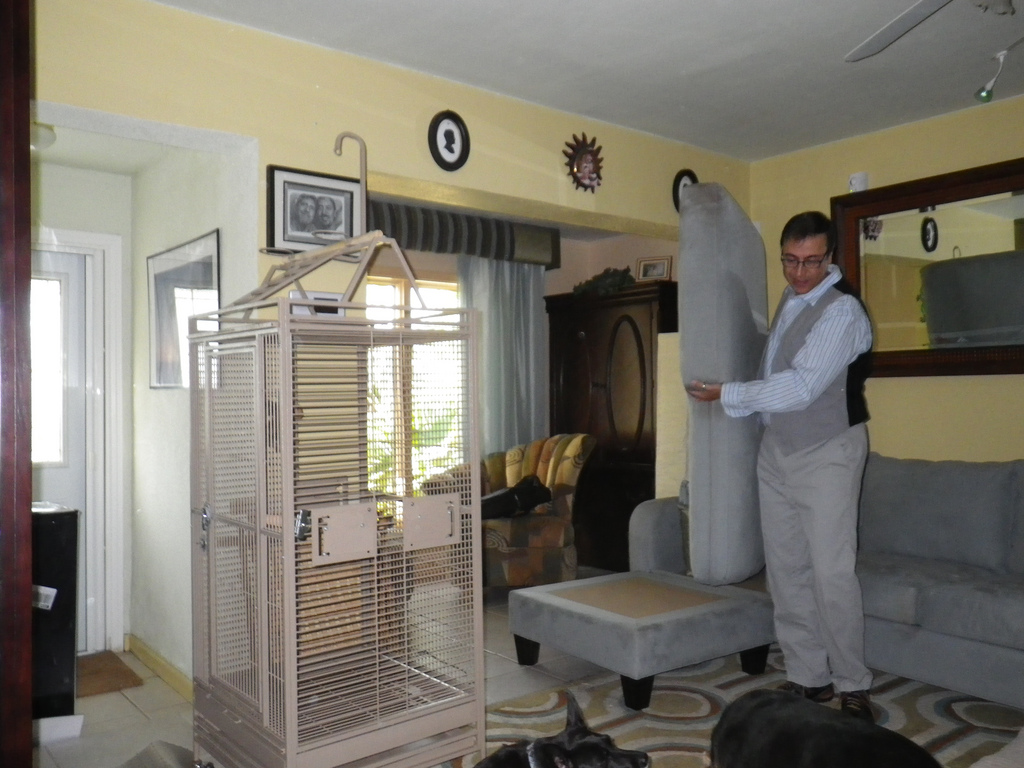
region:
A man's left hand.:
[683, 378, 725, 402]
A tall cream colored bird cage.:
[184, 231, 491, 762]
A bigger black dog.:
[709, 681, 943, 765]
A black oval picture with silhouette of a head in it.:
[425, 109, 471, 174]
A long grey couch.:
[627, 447, 1021, 713]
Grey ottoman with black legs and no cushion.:
[506, 571, 776, 711]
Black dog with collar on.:
[474, 691, 658, 765]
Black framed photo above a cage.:
[261, 163, 369, 263]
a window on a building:
[27, 281, 69, 469]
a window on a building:
[373, 273, 409, 493]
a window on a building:
[412, 273, 467, 477]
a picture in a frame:
[428, 106, 463, 165]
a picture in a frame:
[270, 158, 373, 257]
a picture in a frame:
[141, 232, 231, 392]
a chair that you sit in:
[419, 427, 569, 584]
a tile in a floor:
[100, 676, 183, 712]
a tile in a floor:
[148, 705, 203, 741]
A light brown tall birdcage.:
[148, 126, 534, 763]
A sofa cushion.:
[670, 175, 768, 574]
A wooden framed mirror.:
[817, 150, 1021, 404]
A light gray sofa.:
[534, 348, 1016, 690]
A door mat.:
[78, 646, 145, 701]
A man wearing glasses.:
[694, 215, 891, 712]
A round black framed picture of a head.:
[429, 109, 478, 168]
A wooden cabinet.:
[531, 278, 675, 573]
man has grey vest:
[740, 266, 839, 494]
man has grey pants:
[760, 427, 915, 655]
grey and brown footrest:
[512, 559, 769, 711]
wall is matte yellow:
[283, 56, 385, 161]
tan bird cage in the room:
[177, 224, 573, 752]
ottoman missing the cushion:
[510, 566, 757, 706]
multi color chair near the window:
[431, 405, 628, 590]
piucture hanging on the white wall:
[117, 220, 255, 399]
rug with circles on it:
[355, 622, 1005, 766]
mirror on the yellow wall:
[816, 164, 1020, 390]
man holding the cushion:
[713, 190, 906, 681]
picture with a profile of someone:
[424, 101, 500, 212]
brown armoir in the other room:
[539, 268, 702, 585]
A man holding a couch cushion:
[609, 108, 875, 685]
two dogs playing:
[511, 663, 949, 765]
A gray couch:
[878, 430, 990, 686]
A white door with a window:
[18, 316, 111, 488]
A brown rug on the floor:
[878, 674, 983, 760]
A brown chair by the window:
[405, 389, 612, 612]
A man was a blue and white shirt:
[653, 190, 900, 564]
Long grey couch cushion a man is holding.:
[676, 182, 766, 588]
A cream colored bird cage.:
[186, 232, 490, 767]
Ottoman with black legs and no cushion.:
[509, 574, 772, 707]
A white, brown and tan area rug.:
[426, 634, 1022, 765]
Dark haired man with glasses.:
[686, 208, 874, 724]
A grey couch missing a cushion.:
[625, 451, 1022, 708]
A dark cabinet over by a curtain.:
[543, 281, 676, 569]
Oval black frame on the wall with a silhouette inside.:
[426, 107, 471, 172]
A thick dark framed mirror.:
[827, 156, 1023, 379]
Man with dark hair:
[708, 215, 939, 719]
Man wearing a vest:
[666, 190, 949, 728]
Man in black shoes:
[689, 198, 925, 712]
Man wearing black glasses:
[695, 202, 939, 728]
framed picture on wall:
[105, 200, 268, 419]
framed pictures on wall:
[392, 83, 747, 258]